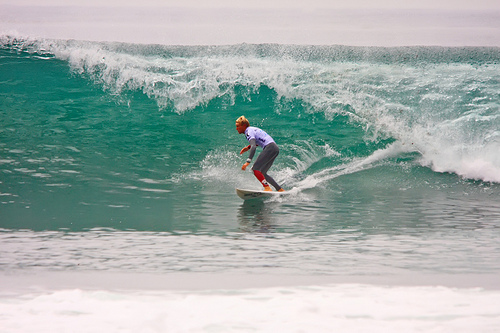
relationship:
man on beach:
[234, 113, 286, 193] [37, 15, 470, 328]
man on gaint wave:
[234, 113, 286, 193] [0, 29, 499, 204]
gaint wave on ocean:
[0, 29, 499, 204] [324, 65, 446, 196]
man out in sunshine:
[234, 113, 286, 193] [21, 16, 497, 325]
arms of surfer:
[236, 134, 258, 169] [227, 112, 293, 193]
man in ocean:
[234, 113, 286, 193] [48, 188, 231, 300]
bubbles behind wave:
[0, 31, 499, 196] [0, 32, 500, 217]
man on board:
[234, 113, 286, 193] [233, 187, 284, 200]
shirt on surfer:
[238, 129, 278, 149] [228, 102, 291, 194]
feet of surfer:
[258, 181, 297, 198] [230, 112, 285, 212]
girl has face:
[236, 115, 284, 192] [234, 121, 246, 136]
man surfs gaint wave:
[232, 113, 284, 191] [0, 29, 499, 204]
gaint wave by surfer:
[0, 29, 499, 204] [225, 110, 284, 197]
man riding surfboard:
[234, 113, 286, 193] [239, 181, 274, 206]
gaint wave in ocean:
[0, 29, 499, 204] [0, 0, 500, 332]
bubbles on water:
[2, 228, 499, 294] [0, 35, 497, 332]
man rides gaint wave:
[234, 113, 286, 193] [0, 29, 499, 204]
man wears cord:
[234, 113, 286, 193] [252, 171, 270, 191]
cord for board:
[252, 171, 270, 191] [236, 188, 294, 203]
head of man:
[232, 115, 251, 135] [234, 113, 286, 193]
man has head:
[234, 113, 286, 193] [232, 115, 251, 135]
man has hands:
[234, 113, 286, 193] [238, 144, 251, 172]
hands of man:
[238, 144, 251, 172] [234, 113, 286, 193]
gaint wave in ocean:
[0, 39, 279, 115] [0, 1, 231, 330]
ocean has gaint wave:
[0, 1, 231, 330] [0, 39, 279, 115]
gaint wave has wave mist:
[0, 29, 499, 204] [176, 141, 253, 193]